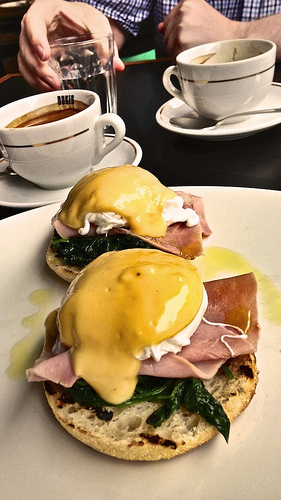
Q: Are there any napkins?
A: No, there are no napkins.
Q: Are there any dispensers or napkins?
A: No, there are no napkins or dispensers.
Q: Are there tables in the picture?
A: Yes, there is a table.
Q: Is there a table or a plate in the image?
A: Yes, there is a table.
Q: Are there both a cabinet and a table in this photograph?
A: No, there is a table but no cabinets.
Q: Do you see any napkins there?
A: No, there are no napkins.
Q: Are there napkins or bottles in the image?
A: No, there are no napkins or bottles.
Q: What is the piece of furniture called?
A: The piece of furniture is a table.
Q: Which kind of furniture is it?
A: The piece of furniture is a table.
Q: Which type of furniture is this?
A: This is a table.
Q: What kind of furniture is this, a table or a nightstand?
A: This is a table.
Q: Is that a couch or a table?
A: That is a table.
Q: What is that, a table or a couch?
A: That is a table.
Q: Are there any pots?
A: No, there are no pots.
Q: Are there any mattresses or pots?
A: No, there are no pots or mattresses.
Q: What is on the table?
A: The glass is on the table.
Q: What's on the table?
A: The glass is on the table.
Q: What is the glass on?
A: The glass is on the table.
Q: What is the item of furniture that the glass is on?
A: The piece of furniture is a table.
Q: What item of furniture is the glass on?
A: The glass is on the table.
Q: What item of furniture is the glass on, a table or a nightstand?
A: The glass is on a table.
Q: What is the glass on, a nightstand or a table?
A: The glass is on a table.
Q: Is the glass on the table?
A: Yes, the glass is on the table.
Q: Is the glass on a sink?
A: No, the glass is on the table.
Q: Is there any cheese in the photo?
A: Yes, there is cheese.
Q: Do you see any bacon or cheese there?
A: Yes, there is cheese.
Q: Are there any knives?
A: No, there are no knives.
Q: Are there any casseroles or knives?
A: No, there are no knives or casseroles.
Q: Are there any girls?
A: No, there are no girls.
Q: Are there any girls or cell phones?
A: No, there are no girls or cell phones.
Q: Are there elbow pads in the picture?
A: No, there are no elbow pads.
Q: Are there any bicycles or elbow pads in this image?
A: No, there are no elbow pads or bicycles.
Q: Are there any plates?
A: Yes, there is a plate.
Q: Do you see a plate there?
A: Yes, there is a plate.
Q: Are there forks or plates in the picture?
A: Yes, there is a plate.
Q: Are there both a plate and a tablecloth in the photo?
A: No, there is a plate but no tablecloths.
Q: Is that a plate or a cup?
A: That is a plate.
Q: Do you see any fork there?
A: No, there are no forks.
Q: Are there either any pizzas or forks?
A: No, there are no forks or pizzas.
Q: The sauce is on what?
A: The sauce is on the plate.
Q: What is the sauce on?
A: The sauce is on the plate.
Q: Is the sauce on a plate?
A: Yes, the sauce is on a plate.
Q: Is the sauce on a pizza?
A: No, the sauce is on a plate.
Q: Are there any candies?
A: No, there are no candies.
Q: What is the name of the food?
A: The food is a bun.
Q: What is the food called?
A: The food is a bun.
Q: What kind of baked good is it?
A: The food is a bun.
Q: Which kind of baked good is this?
A: This is a bun.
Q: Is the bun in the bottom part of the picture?
A: Yes, the bun is in the bottom of the image.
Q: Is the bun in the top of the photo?
A: No, the bun is in the bottom of the image.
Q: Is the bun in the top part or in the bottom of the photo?
A: The bun is in the bottom of the image.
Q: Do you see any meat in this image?
A: Yes, there is meat.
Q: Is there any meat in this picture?
A: Yes, there is meat.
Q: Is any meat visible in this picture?
A: Yes, there is meat.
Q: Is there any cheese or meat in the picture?
A: Yes, there is meat.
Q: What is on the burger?
A: The meat is on the burger.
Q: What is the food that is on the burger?
A: The food is meat.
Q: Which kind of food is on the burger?
A: The food is meat.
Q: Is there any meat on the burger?
A: Yes, there is meat on the burger.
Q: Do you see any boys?
A: No, there are no boys.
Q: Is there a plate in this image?
A: Yes, there is a plate.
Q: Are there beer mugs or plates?
A: Yes, there is a plate.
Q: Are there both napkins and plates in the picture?
A: No, there is a plate but no napkins.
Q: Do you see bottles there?
A: No, there are no bottles.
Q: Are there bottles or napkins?
A: No, there are no bottles or napkins.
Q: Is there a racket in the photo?
A: No, there are no rackets.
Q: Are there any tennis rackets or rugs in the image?
A: No, there are no tennis rackets or rugs.